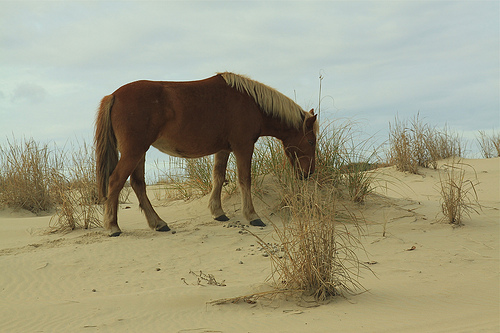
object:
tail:
[91, 94, 113, 209]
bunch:
[208, 151, 380, 307]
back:
[117, 71, 270, 101]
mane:
[215, 70, 320, 136]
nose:
[300, 167, 314, 180]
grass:
[0, 130, 68, 217]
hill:
[0, 156, 499, 333]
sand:
[353, 233, 500, 313]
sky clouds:
[425, 65, 485, 100]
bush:
[430, 153, 486, 229]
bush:
[372, 109, 471, 176]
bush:
[326, 127, 418, 205]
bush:
[42, 164, 105, 236]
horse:
[92, 70, 318, 237]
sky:
[0, 0, 500, 186]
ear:
[309, 108, 315, 116]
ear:
[306, 113, 318, 127]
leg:
[104, 144, 152, 237]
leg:
[130, 152, 170, 231]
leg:
[207, 150, 230, 221]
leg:
[230, 141, 266, 227]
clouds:
[88, 0, 395, 69]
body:
[136, 78, 274, 150]